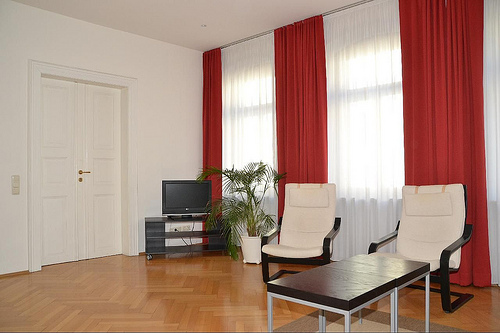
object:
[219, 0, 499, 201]
window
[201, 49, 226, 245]
curtain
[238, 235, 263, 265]
planter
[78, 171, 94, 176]
handle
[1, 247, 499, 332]
herringbone design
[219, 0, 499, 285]
curtains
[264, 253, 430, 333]
table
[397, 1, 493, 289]
curtain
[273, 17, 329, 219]
curtain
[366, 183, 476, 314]
chair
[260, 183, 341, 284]
chair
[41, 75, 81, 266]
doors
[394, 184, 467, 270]
back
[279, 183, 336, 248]
back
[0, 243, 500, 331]
floor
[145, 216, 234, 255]
cabinet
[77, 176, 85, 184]
knobs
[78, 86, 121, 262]
doors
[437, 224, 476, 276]
handle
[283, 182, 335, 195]
top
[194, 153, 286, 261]
palm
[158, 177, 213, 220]
tv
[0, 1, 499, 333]
room